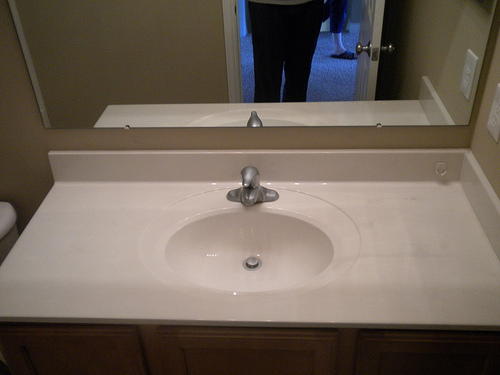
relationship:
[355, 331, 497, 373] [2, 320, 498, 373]
door for cabinet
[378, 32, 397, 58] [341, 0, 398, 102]
knob on door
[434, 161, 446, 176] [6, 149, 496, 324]
device on sink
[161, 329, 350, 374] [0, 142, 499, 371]
door for cabinet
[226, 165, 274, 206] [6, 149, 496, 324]
metal part of sink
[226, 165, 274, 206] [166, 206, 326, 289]
metal part on sink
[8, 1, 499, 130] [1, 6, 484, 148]
mirror on wall